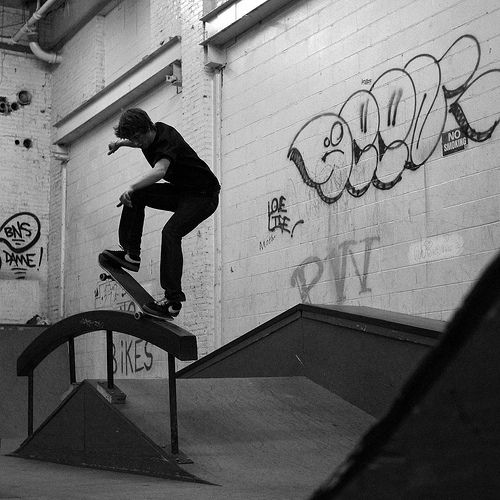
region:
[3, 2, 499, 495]
the photograph is black and white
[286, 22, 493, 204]
the graffiti on the wall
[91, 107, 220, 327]
the man doing a trick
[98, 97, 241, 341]
the man on the skateboard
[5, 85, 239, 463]
the man riding the rail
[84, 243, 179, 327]
the skateboard is black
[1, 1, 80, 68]
pipes on the ceiling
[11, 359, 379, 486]
the ramp under the man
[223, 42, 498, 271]
the wall is brick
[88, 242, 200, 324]
the man wearing sneakers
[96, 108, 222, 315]
a man on a skateboard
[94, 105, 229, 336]
a man doing a trick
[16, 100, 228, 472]
a man grinding a rail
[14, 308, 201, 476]
a black rail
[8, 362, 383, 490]
a small skateboard ramp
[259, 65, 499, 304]
graffiti on the wall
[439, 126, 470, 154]
a no smoking sign on the wall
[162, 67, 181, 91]
a white security camera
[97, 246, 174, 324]
a skateboard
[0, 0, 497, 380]
a white brick wall background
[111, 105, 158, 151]
the head of a person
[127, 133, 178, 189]
the arm of a person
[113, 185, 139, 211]
the hand of a person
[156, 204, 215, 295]
the leg of a person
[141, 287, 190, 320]
a shoe on the person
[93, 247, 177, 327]
a skateboard under the person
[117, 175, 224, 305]
a pair of pants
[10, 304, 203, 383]
a railing under the skateboard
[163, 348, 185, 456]
a metal bar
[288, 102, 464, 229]
black and white graffiti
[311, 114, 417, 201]
black and white graffiti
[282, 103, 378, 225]
black and white graffiti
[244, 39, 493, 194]
graffiti is on the wall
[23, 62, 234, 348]
the man is skateboarding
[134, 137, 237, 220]
boy's shirt is black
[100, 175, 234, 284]
boy's pants are black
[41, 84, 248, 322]
boy is skating on ramp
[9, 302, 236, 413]
the ramp is black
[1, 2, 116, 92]
the pipes are white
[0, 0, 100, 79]
pipes are on ceiling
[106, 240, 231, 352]
boy's shoes are black